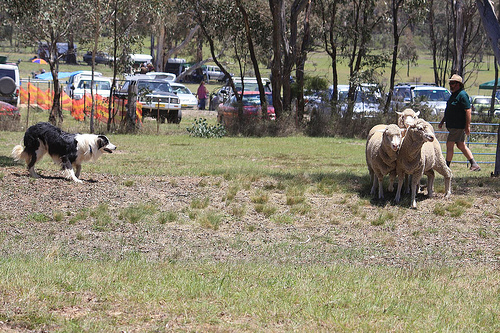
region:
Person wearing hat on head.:
[447, 66, 472, 93]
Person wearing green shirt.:
[441, 92, 469, 119]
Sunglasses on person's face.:
[440, 78, 463, 89]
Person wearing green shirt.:
[431, 90, 478, 125]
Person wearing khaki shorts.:
[440, 117, 478, 163]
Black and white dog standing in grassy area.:
[11, 113, 131, 190]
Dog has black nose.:
[106, 143, 128, 155]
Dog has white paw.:
[54, 163, 91, 190]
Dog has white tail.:
[8, 138, 43, 168]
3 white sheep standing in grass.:
[377, 99, 449, 199]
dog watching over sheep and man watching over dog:
[11, 71, 481, 211]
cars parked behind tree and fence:
[5, 10, 490, 125]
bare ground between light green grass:
[5, 131, 470, 316]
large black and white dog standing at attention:
[10, 115, 117, 180]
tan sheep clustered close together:
[360, 105, 450, 205]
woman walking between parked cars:
[180, 75, 216, 107]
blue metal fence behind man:
[420, 115, 495, 175]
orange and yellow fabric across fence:
[15, 76, 143, 123]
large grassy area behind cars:
[90, 17, 495, 78]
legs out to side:
[422, 150, 452, 201]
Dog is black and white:
[4, 115, 130, 193]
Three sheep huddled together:
[356, 103, 459, 211]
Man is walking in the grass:
[433, 68, 478, 175]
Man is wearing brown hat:
[437, 70, 482, 176]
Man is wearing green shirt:
[438, 70, 479, 175]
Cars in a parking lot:
[218, 65, 448, 130]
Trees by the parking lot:
[238, 25, 398, 145]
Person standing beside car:
[192, 78, 212, 110]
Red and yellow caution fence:
[13, 76, 155, 133]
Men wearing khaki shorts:
[434, 70, 485, 187]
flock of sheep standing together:
[276, 63, 498, 245]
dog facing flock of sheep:
[3, 83, 485, 243]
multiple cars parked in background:
[23, 3, 488, 208]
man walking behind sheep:
[328, 35, 498, 217]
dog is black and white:
[3, 103, 140, 228]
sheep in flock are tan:
[339, 79, 469, 210]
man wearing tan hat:
[439, 56, 474, 104]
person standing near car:
[183, 56, 245, 124]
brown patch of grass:
[5, 133, 475, 322]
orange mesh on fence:
[0, 59, 162, 154]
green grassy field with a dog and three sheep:
[5, 105, 491, 329]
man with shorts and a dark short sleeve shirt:
[431, 74, 481, 169]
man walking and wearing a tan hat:
[446, 75, 466, 96]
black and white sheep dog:
[11, 120, 117, 189]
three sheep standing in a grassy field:
[359, 106, 458, 213]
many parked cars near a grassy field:
[6, 34, 495, 131]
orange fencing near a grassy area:
[14, 82, 142, 124]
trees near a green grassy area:
[102, 0, 407, 120]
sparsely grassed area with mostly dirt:
[5, 162, 483, 260]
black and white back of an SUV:
[0, 62, 25, 113]